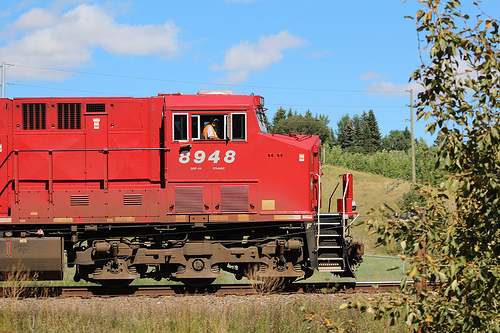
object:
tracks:
[0, 279, 465, 300]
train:
[1, 89, 361, 296]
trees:
[268, 104, 425, 183]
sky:
[1, 1, 493, 107]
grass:
[4, 299, 486, 332]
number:
[179, 150, 191, 165]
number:
[174, 149, 235, 163]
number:
[191, 148, 209, 168]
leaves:
[273, 104, 398, 163]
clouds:
[211, 29, 311, 87]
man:
[201, 116, 223, 142]